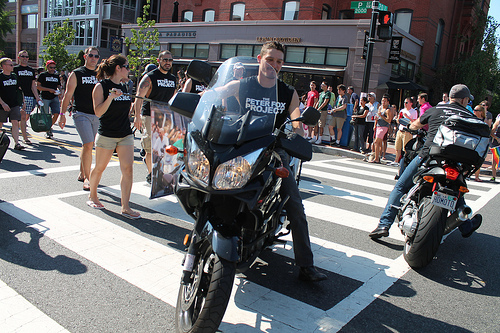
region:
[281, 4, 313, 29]
Small Window on a building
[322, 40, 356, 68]
Small Window on a building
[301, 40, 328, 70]
Small Window on a building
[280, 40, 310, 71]
Small Window on a building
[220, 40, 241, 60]
Small Window on a building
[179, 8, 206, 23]
Small Window on a building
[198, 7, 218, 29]
Small Window on a building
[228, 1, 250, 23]
Small Window on a building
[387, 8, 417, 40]
Small Window on a building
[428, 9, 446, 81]
Small Window on a building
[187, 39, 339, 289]
Man is on a motorcycle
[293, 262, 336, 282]
Man is wearing shoes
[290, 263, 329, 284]
Man is wearing black shoes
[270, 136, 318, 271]
Man is wearing pants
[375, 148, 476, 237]
Man is wearing jeans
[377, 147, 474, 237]
Man is wearing blue jeans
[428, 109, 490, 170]
Bag on back of motorcycle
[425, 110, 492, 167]
Black and white bag on back of motorcycle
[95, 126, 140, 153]
Woman is wearing shorts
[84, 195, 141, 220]
Woman is wearing sandals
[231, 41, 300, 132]
man on a motorcycle with a black and white shirt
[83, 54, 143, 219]
woman wearing flip flops and shorts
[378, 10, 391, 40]
do not walk pedestrian signal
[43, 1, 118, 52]
building with many glass windows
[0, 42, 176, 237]
group of people walking on a city street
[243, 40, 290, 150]
man on a motorcycle wearing a "Peter Fox Project" shirt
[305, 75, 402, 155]
group of people on the side of the street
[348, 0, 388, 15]
green street signs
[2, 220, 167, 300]
white painted crosswalk on a street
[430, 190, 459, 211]
license plate on the back of a motorcycle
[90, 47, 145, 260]
PErson walking on pavement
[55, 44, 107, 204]
PErson walking on pavement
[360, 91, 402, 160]
PErson walking on pavement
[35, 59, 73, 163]
PErson walking on pavement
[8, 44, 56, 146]
PErson walking on pavement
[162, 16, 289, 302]
Person on a motorcycle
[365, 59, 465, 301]
Person on a motorcycle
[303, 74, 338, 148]
Person on a motorcycle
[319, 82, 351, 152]
Person on a motorcycle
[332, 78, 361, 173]
Person on a motorcycle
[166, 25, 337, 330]
man sitting on a motorcycle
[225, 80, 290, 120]
white letters on man's shirt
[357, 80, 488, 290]
man sitting on a motorcycle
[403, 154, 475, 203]
red tail lights on motorcycle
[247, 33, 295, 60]
man's hair is brown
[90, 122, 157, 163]
woman wearing brown shorts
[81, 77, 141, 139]
woman's shirt is black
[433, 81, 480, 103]
man wearing a hat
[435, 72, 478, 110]
the hat is gray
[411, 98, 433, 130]
man's shirt is pink